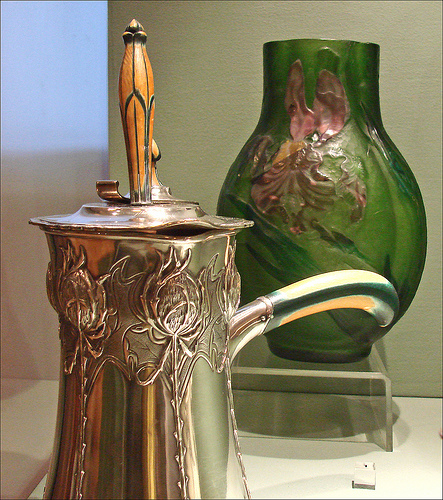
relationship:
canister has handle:
[29, 15, 400, 499] [114, 17, 166, 207]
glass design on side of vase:
[255, 48, 371, 240] [217, 36, 431, 366]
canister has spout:
[29, 15, 400, 499] [230, 256, 400, 364]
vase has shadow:
[217, 36, 431, 366] [231, 374, 400, 444]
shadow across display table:
[231, 374, 400, 444] [2, 369, 442, 499]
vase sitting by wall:
[217, 36, 431, 366] [105, 2, 440, 408]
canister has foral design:
[29, 15, 400, 499] [120, 245, 219, 499]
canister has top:
[29, 15, 400, 499] [34, 201, 258, 242]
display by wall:
[217, 337, 401, 451] [105, 2, 440, 408]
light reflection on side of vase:
[300, 115, 367, 187] [217, 36, 431, 366]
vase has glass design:
[217, 36, 431, 366] [255, 48, 371, 240]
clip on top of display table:
[349, 470, 375, 493] [2, 369, 442, 499]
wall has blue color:
[1, 1, 108, 500] [2, 2, 119, 154]